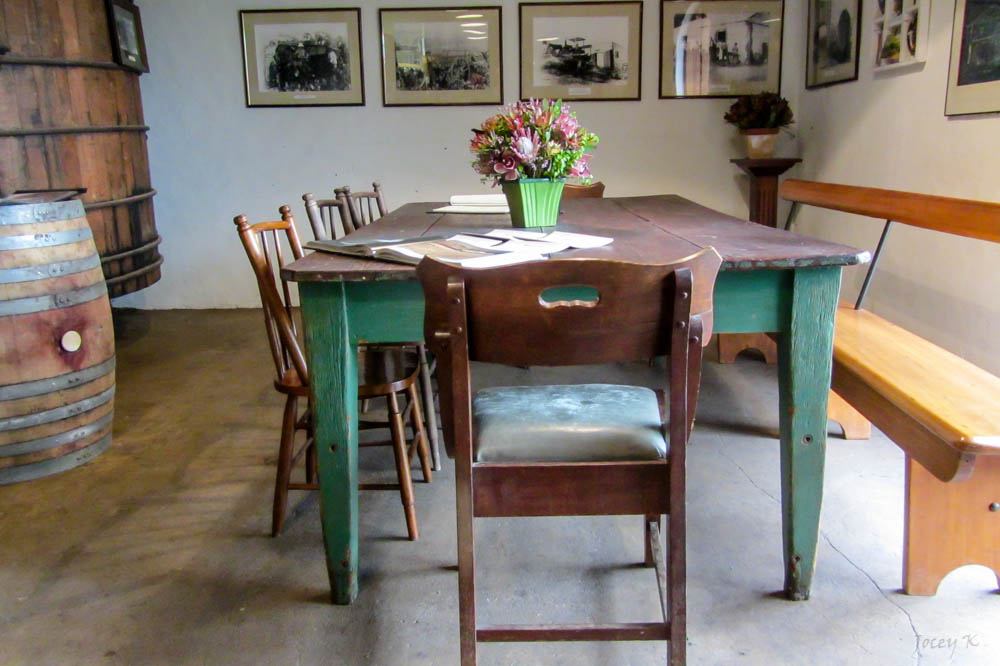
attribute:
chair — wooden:
[410, 238, 726, 663]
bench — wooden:
[818, 269, 967, 430]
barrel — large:
[23, 245, 208, 485]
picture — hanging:
[227, 0, 383, 172]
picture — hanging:
[403, 43, 561, 110]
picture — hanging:
[650, 0, 797, 134]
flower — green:
[484, 96, 629, 292]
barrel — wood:
[5, 171, 121, 492]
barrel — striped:
[6, 190, 120, 480]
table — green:
[284, 185, 867, 601]